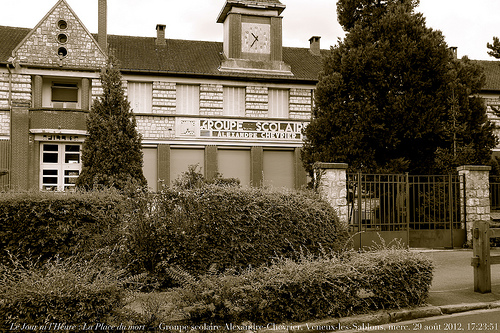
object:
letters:
[202, 121, 309, 139]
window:
[173, 82, 199, 115]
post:
[468, 220, 499, 294]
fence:
[467, 215, 500, 292]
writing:
[9, 319, 498, 332]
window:
[265, 84, 292, 122]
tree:
[74, 50, 148, 225]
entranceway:
[40, 142, 82, 193]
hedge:
[6, 247, 433, 326]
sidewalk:
[403, 232, 498, 310]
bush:
[0, 186, 123, 264]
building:
[0, 0, 497, 230]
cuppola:
[153, 37, 307, 199]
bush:
[119, 179, 338, 290]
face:
[221, 12, 290, 76]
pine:
[77, 53, 147, 191]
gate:
[345, 162, 465, 252]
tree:
[297, 0, 500, 213]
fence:
[344, 168, 466, 249]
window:
[41, 142, 58, 163]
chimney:
[156, 23, 167, 44]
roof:
[1, 24, 498, 96]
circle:
[57, 47, 67, 56]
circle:
[56, 33, 67, 43]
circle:
[59, 20, 68, 30]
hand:
[250, 38, 259, 47]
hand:
[249, 32, 258, 38]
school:
[0, 0, 500, 250]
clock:
[241, 23, 271, 54]